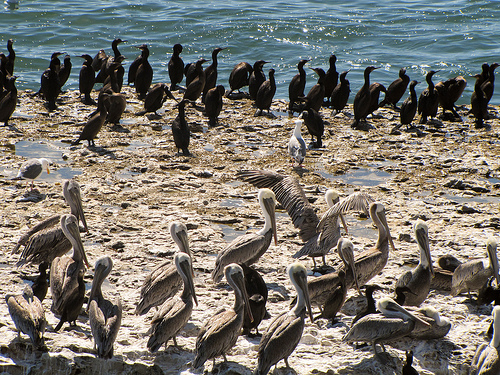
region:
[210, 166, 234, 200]
part of a beaxh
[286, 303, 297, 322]
part of a line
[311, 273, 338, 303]
par tof a wing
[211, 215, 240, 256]
par tof a watyer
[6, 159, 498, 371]
pelicans on the beach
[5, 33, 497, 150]
black birds on the beach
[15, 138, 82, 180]
puddle of water in the sand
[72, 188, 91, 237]
long sharp point bird bill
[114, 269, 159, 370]
claw prints in the sand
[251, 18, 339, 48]
reflection of sun on the water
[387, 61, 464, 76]
foam from waves splashing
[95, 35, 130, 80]
bird craning its neck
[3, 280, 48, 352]
bird with its head turned around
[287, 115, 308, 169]
seagull near the pelicans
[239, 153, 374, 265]
white bird with his wings spread out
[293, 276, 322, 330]
long beak on white and gray bird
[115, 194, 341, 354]
white and gray birds in the sand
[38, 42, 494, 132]
black feathered birds in the sand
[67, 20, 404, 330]
two different kinds of birds at the beach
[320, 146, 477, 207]
water puddled up in the sand on the beach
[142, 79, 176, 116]
black feathered bird on sandy beach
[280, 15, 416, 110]
bubbles floating on the water near the sand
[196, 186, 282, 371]
black bird standing in between two white and gray birds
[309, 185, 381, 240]
extended wing covered in gray feathers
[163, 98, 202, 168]
The bird is on the shore.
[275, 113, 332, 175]
The bird is on the shore.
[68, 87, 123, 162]
The bird is on the shore.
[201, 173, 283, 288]
The bird is on the shore.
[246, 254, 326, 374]
The bird is on the shore.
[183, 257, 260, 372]
The bird is on the shore.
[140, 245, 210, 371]
The bird is on the shore.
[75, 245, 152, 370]
The bird is on the shore.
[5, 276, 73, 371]
The bird is on the shore.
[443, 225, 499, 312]
The bird is on the shore.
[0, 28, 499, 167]
group of black sea birds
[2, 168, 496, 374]
group of light brown pelicans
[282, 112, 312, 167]
white and grey sea gull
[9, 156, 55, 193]
white and grey sea gull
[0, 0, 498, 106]
calm blue green water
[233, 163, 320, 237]
left side brown pelican wing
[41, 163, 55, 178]
orange sea gull beak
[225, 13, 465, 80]
white foam floating on the water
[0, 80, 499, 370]
wet sea weed covered ground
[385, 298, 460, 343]
light brown pelican laying down